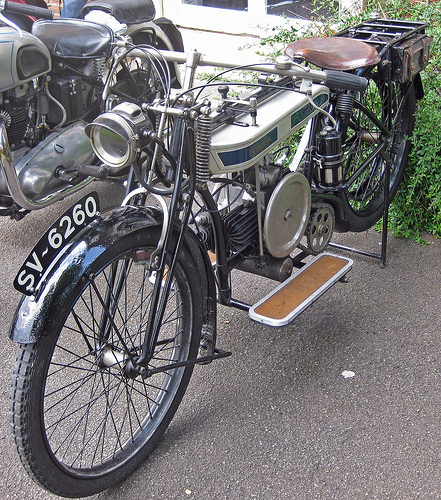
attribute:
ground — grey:
[2, 180, 436, 498]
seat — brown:
[267, 16, 391, 89]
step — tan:
[256, 248, 354, 333]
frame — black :
[89, 186, 186, 381]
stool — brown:
[239, 247, 349, 345]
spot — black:
[342, 15, 430, 60]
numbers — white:
[13, 190, 98, 293]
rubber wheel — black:
[341, 53, 415, 226]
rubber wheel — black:
[11, 230, 205, 497]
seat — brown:
[283, 34, 381, 73]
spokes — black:
[41, 272, 189, 460]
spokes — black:
[353, 101, 401, 209]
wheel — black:
[11, 199, 210, 498]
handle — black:
[271, 62, 378, 96]